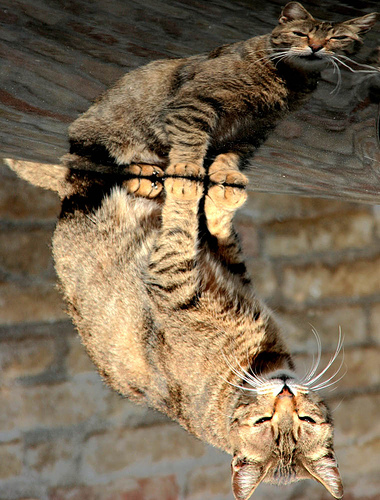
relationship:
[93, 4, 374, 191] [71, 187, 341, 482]
reflection of a cat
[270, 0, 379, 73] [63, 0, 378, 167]
head of a cat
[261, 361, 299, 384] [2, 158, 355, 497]
mouth of a cat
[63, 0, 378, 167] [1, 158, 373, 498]
cat in water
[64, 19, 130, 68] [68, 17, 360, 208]
wall behind cat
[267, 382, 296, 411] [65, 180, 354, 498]
nose of a cat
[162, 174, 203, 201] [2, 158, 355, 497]
paw of a cat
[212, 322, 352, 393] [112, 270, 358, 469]
whiskers of cat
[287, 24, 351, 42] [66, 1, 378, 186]
eyes of cat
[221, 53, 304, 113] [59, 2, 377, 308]
chest of cat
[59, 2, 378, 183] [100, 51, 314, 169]
reflection of cat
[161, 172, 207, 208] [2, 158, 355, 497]
paw of cat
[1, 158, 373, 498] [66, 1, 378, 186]
water of cat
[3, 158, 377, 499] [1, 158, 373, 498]
reflection in water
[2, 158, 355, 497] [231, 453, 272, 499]
cat has ear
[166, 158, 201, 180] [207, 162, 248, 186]
paw touching paw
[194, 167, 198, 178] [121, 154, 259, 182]
claw on paw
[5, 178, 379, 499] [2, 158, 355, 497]
wall behind cat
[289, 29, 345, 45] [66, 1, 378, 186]
eyes of cat